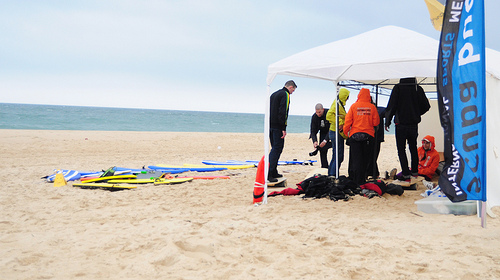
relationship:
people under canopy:
[342, 87, 380, 186] [262, 25, 499, 216]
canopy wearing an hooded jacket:
[262, 25, 499, 216] [343, 86, 382, 137]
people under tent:
[328, 85, 433, 159] [305, 22, 406, 78]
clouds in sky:
[76, 65, 235, 106] [0, 7, 270, 68]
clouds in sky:
[29, 49, 154, 106] [19, 13, 264, 137]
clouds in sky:
[23, 14, 300, 72] [5, 4, 440, 114]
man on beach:
[383, 131, 436, 184] [0, 129, 499, 280]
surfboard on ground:
[205, 154, 246, 168] [192, 170, 240, 211]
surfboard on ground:
[165, 161, 225, 174] [192, 170, 240, 211]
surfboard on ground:
[83, 179, 131, 205] [192, 170, 240, 211]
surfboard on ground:
[273, 153, 317, 173] [192, 170, 240, 211]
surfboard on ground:
[155, 165, 189, 177] [192, 170, 240, 211]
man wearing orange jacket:
[384, 134, 442, 181] [415, 133, 440, 180]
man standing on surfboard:
[267, 80, 298, 182] [258, 167, 302, 189]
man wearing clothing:
[385, 76, 431, 181] [390, 78, 427, 181]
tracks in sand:
[155, 232, 223, 277] [9, 129, 491, 271]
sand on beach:
[9, 129, 491, 271] [5, 104, 495, 278]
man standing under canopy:
[267, 80, 298, 182] [262, 23, 498, 213]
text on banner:
[456, 77, 482, 155] [432, 2, 488, 206]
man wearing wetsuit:
[307, 103, 341, 181] [307, 108, 329, 170]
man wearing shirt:
[267, 80, 298, 182] [270, 87, 290, 131]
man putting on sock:
[308, 103, 332, 168] [307, 147, 335, 162]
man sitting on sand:
[384, 134, 442, 181] [9, 129, 491, 271]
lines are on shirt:
[282, 89, 293, 125] [266, 88, 291, 136]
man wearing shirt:
[265, 78, 299, 193] [266, 88, 291, 136]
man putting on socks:
[308, 103, 332, 168] [307, 148, 319, 158]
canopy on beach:
[262, 23, 498, 213] [1, 126, 498, 277]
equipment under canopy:
[276, 165, 410, 200] [265, 26, 452, 186]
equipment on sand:
[52, 154, 306, 188] [126, 200, 287, 277]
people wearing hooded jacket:
[342, 87, 380, 186] [343, 87, 380, 138]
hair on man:
[310, 97, 328, 121] [302, 96, 330, 122]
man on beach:
[267, 80, 298, 182] [5, 187, 497, 278]